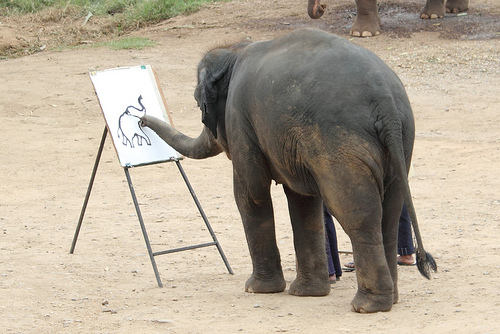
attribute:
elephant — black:
[119, 23, 462, 298]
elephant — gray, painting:
[136, 19, 443, 316]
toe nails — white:
[243, 286, 258, 296]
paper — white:
[92, 62, 189, 178]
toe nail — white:
[345, 26, 353, 36]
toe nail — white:
[350, 27, 361, 40]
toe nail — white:
[359, 27, 374, 38]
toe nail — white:
[371, 29, 384, 39]